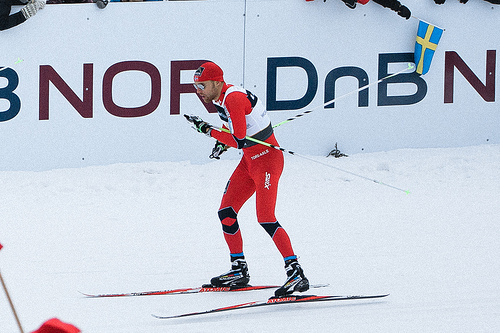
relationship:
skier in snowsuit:
[74, 55, 424, 323] [217, 82, 294, 259]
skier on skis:
[74, 55, 424, 323] [80, 283, 389, 320]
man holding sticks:
[182, 58, 312, 300] [183, 64, 423, 192]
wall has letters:
[3, 1, 498, 154] [2, 51, 499, 120]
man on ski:
[186, 61, 304, 291] [148, 287, 390, 316]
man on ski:
[186, 61, 304, 291] [70, 285, 331, 297]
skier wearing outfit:
[165, 55, 330, 322] [202, 81, 300, 263]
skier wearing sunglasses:
[74, 55, 424, 323] [187, 81, 210, 91]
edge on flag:
[413, 15, 420, 69] [412, 18, 442, 73]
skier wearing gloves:
[74, 55, 424, 323] [173, 108, 228, 162]